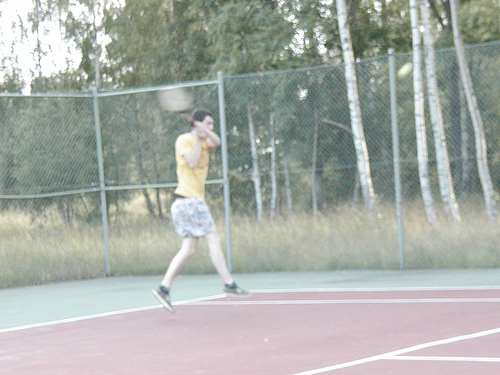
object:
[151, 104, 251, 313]
man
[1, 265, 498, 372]
court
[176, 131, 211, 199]
shirt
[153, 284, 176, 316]
shoe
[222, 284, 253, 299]
shoe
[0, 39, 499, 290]
fence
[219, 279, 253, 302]
right-foot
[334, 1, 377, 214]
trunk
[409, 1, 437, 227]
trunk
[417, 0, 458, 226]
trunk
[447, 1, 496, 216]
trunk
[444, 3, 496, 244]
tree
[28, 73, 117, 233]
tree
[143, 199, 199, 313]
leg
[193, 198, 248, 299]
leg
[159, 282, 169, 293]
sock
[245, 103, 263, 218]
trunk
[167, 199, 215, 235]
shorts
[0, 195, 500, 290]
grass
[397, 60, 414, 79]
ball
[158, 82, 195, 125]
racquet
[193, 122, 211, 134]
hand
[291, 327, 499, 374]
lines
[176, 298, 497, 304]
lines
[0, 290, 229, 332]
lines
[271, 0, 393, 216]
tree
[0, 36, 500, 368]
tennis court